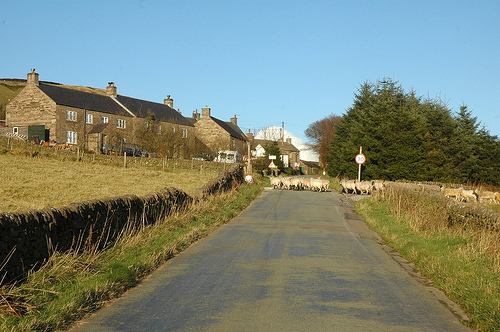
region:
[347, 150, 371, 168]
the sign is round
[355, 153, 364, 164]
the numbers are black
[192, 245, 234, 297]
the road is black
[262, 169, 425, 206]
the cows are crossing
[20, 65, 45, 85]
the building has a chimney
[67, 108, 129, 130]
the building has windows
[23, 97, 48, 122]
the building is brown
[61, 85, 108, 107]
the roof is black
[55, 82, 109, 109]
the roof is sloped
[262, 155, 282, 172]
the sign is triangular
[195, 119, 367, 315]
the road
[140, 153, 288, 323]
the road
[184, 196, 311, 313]
the road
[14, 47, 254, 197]
the building is brown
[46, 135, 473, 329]
the road is dirty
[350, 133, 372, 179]
sign next to road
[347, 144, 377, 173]
the sign is red and white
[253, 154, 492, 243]
animals crossing the road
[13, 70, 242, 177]
building is made of brick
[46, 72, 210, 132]
the roof is black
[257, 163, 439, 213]
the animals are white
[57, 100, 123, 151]
windows on building are white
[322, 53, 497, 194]
trees across from building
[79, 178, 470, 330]
a street for cars to go down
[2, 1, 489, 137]
the bright blue cloudless sky above everything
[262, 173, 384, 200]
a herd of sheep walking around the street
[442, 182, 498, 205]
some more sheep walking around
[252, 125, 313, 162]
something white in the background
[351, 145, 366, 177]
a sign at the end of the road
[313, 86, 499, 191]
trees at the end of the road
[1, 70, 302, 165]
the buildings and houses in the background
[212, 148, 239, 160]
a car parked in the house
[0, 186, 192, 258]
a fence by the road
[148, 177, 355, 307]
a road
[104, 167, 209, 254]
a road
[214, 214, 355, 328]
a road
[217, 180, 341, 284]
a road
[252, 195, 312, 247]
a road